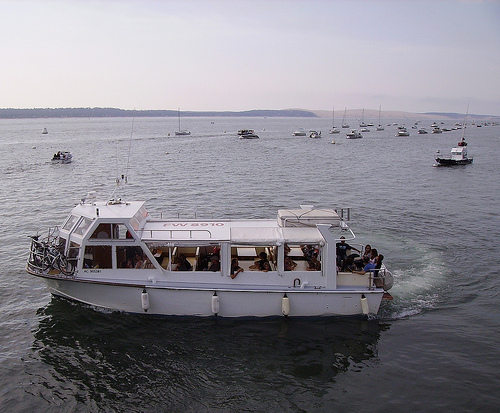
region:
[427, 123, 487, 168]
a boat in the water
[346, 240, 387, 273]
people on the boat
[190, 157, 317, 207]
the oceans water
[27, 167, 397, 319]
the boat is white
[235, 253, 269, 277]
people in the boat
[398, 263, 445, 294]
the water has bubbles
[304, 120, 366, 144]
boats in the water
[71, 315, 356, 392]
reflection of the boat in the water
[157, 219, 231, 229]
letters and numbers on the boat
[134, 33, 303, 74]
the sky is clear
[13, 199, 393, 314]
a white boat on the water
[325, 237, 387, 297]
people sitting on a boat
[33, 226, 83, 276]
bikes on a boat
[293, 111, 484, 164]
several boats in the water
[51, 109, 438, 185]
a large body of water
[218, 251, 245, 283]
a man hanging his arm out of a window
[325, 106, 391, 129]
four sail boats on the water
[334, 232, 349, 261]
a man wearing a black shirt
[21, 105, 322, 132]
land next to the water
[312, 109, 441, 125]
a hill side next to the water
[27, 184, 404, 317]
Boat in the water.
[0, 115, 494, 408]
Gray water in the forefront.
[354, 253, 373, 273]
Person in a blue shirt.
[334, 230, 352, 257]
Person in a black shirt.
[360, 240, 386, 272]
People sitting in the boat.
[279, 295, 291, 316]
White buoy on the boat.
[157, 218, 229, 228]
Red writing on the boat.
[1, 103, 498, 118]
Land in the background.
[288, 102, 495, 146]
Multiple boats in the background.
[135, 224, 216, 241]
Railing on the boat.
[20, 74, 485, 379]
photograph of many boats in the water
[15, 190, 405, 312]
white passenger boat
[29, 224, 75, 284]
bicycles on the front of the boat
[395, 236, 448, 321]
small waves made by boats motor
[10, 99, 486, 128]
land in the distance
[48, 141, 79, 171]
small motorboat with people on board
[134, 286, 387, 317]
four white safety bouys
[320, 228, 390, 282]
people sitting in the back of the boat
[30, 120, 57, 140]
white bouy in the water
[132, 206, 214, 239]
silver railings on top level of boat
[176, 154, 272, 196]
Part of the water.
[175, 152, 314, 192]
Part of a body of water.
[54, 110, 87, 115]
Part of land by the water.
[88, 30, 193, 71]
Part of a sky.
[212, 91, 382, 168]
Many boats in the water.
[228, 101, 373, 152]
Many small boats in the water.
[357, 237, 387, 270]
People sitting on a boat.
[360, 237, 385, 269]
Two people sitting on a boat.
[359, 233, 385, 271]
Two people sitting on a large boat.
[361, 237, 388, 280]
Two people sitting on a large white boat.